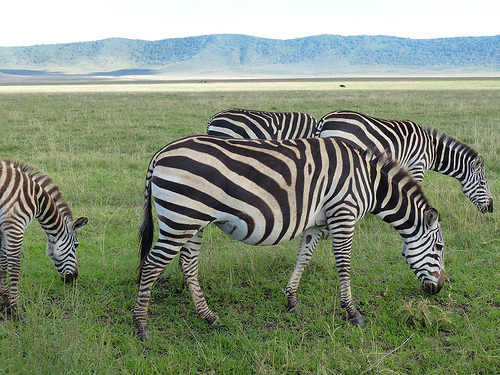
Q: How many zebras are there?
A: Four.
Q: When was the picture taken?
A: Daytime.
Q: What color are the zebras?
A: Black and white.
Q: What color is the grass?
A: Green.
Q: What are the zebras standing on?
A: Grass.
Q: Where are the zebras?
A: On the grass.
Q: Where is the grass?
A: Under the zebras.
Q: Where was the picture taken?
A: In an open field.